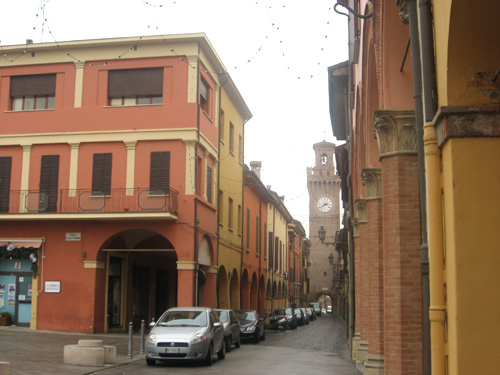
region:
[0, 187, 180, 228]
balcony attached to building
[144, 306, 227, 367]
car parked in front of car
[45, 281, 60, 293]
white sign mounted on building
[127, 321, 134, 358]
metal pole to the left of car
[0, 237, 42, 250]
awning above window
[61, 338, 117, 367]
round concrete barrier next to street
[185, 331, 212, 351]
light on a car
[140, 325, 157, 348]
light on a car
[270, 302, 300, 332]
car on a street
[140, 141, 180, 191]
window on a building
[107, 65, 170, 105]
window on a building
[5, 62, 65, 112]
window on a building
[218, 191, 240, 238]
window on a building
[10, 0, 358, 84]
string of christmas lights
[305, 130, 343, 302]
tall beige clock tower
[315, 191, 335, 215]
white clock face with black hands and numbers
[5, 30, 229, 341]
red building with cream trim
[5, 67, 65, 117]
large window with half drawn shades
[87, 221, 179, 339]
arched doorway on red building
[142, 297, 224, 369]
silver compact car parked in front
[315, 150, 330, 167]
bell hanging inside clock tower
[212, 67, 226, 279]
metal downspout of rain gutter on red building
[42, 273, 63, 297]
white sign on front of red building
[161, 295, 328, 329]
the cars are parked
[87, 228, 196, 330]
arch in the building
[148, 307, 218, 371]
the car is silver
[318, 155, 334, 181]
bell in the tower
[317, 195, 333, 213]
numbers on the clock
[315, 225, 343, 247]
lamp is on pole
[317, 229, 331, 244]
the lamp is black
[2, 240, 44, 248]
the awning is orange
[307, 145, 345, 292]
the tower is stone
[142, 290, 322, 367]
row of cars parked on narrow street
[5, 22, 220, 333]
red brick building on corner with terrace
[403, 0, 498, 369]
yellow building in foreground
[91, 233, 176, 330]
rounded archway in brick building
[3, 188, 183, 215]
black metal terrace on brick building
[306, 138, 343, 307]
stone clock tower at end of narrow road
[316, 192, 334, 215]
round white face in clock tower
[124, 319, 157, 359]
silver poles for parking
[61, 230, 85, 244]
small white and black street sign on building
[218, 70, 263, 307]
yellow building with archway entrances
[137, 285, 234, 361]
this is a car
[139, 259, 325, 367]
cars parked on road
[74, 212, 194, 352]
archway on the building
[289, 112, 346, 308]
clock tower in background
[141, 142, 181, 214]
A window on a building.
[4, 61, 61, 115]
A window on a building.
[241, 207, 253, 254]
A window on a building.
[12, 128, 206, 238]
windows on the building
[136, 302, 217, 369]
front of the car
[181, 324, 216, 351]
light on front of car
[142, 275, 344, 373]
many cars lined up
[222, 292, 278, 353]
dark car on the cement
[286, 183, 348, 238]
round clock on building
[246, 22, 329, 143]
sky above the building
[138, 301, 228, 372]
silver car parked outside of building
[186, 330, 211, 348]
headlight on front of car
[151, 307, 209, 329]
windshield on front of car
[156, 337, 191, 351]
vent on front of car